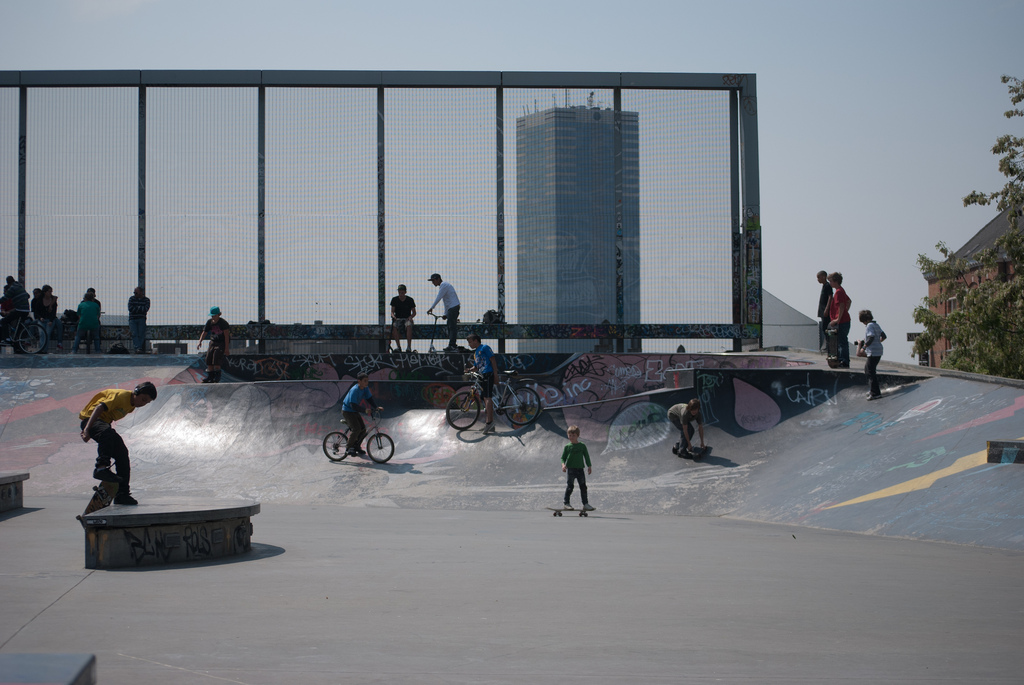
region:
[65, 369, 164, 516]
The boy is on his skateboard.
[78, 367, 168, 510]
The boy is wearing a yellow shirt.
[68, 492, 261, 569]
There is graffiti written on the ramp.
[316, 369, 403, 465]
The boy is riding his bike.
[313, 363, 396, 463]
The boy is wearing a blue shirt.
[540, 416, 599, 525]
The boy is on his skateboard.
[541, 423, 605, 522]
The boy is wearing a green shirt.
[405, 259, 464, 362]
The boy is on a scooter.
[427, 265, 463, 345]
The boy is wearing a white shirt.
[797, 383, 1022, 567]
Graffiti is written on the ramp.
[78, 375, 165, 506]
a boy standing on top of the ramp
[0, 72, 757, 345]
the fence on the side of the skate park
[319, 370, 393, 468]
a boy riding the bike in the skate park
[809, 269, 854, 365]
two boys standing on the edge of the park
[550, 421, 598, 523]
a young boy riding the skateboard in the middle of the skatepark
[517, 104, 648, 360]
a tall building in the background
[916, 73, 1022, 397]
a green leafy tree standing off to the side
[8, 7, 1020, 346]
the blue sky above everything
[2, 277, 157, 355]
a group of people standing by the fence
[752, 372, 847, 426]
the graffiti on the wall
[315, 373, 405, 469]
CHILD WEARING BLUE SHIRT ON BIKE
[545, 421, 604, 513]
CHILD WEARING GREEN SHIRT ON SKATEBOARD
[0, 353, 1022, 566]
GRAFFITI STREET ART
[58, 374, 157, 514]
CHILD IN YELLOW SHIRT DOING SKATEBOARD TRICKS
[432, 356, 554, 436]
MOUNTAIN BIKE AT SKATEPARK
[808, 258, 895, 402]
PEOPLE WATCHING SKATEBOARD TRICKS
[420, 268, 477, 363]
MAN WITH SCOOTER AT SKATEPARK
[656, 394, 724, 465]
CHILD DOING TRICKS ON SKATEBOARD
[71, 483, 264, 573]
BENCH USED BY SKATEBOARDERS TO DO TRICKS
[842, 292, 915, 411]
man on in skateboard park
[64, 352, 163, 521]
board on a skate board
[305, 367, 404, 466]
boy on a bike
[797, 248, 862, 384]
boys in a skateboard park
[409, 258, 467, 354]
boy in a skate park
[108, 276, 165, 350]
man in a skate park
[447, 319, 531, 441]
boy on a bike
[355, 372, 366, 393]
person has a head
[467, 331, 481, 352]
person has a head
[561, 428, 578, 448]
person has a head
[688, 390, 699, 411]
person has a head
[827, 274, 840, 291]
person has a head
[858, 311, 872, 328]
person has a head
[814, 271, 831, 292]
person has a head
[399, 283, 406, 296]
person has a head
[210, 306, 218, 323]
person has a head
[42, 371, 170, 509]
boy skating at skateboard park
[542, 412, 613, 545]
boy skating at skateboard park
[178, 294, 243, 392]
boy skating at skateboard park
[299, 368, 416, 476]
boy riding at skateboard park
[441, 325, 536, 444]
boy riding at skateboard park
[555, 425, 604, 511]
A person is standing up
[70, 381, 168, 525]
A person is standing up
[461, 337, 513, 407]
A person is standing up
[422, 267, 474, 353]
A person is standing up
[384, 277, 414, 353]
A person is standing up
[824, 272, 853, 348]
A person is standing up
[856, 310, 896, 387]
A person is standing up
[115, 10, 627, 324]
the fence is metal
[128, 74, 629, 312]
the fence is chain link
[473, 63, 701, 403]
the tower is blue